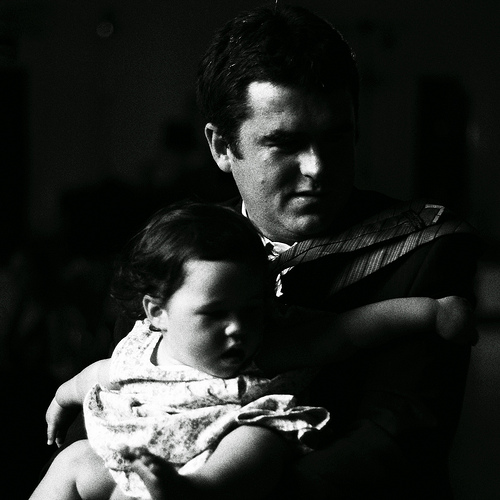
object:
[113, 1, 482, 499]
man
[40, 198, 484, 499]
child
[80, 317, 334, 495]
dress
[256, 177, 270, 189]
pimple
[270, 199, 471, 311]
tie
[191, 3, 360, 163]
hair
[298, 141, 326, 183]
nose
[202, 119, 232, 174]
ear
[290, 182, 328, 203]
mouth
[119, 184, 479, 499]
jacket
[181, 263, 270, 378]
face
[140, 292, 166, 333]
right ear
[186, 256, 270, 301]
forehead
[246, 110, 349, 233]
face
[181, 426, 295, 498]
leg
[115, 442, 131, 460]
toe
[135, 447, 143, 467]
toe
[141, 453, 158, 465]
toe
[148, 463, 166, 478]
toe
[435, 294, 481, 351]
hand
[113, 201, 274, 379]
head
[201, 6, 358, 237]
head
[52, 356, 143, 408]
arm